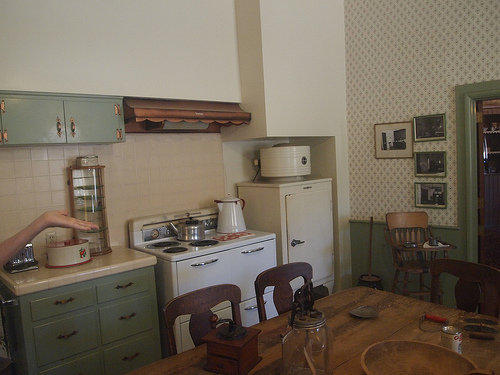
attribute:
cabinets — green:
[18, 80, 160, 190]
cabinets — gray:
[6, 91, 135, 154]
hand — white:
[8, 204, 117, 264]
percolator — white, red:
[210, 193, 251, 236]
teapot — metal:
[173, 213, 209, 247]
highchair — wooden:
[373, 198, 443, 294]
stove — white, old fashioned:
[130, 205, 286, 350]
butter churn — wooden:
[348, 209, 384, 287]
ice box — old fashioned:
[235, 173, 342, 305]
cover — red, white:
[44, 236, 96, 268]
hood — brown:
[119, 87, 257, 143]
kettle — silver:
[164, 213, 209, 245]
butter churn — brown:
[346, 209, 386, 287]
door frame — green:
[448, 78, 484, 301]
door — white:
[284, 180, 331, 292]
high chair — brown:
[379, 207, 453, 297]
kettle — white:
[213, 191, 249, 240]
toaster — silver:
[6, 236, 42, 276]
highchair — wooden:
[381, 204, 431, 282]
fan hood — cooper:
[119, 94, 255, 139]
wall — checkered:
[344, 0, 484, 305]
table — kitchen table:
[130, 285, 499, 373]